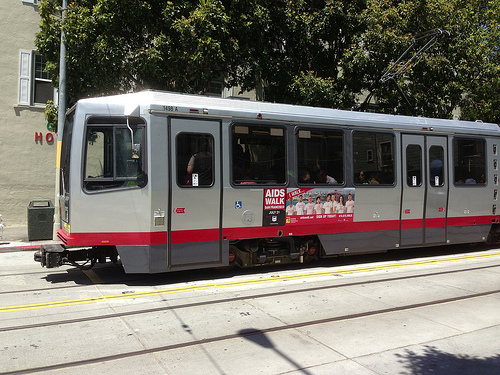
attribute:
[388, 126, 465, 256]
door — is closed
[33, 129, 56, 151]
h o — red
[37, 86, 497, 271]
streetcar — is red, is white, is gray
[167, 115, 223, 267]
door — white, gray, red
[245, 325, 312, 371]
shadow — power lines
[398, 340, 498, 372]
shadow — power lines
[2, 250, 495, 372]
shadow — power lines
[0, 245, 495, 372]
pavement — gray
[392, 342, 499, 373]
shadow — tree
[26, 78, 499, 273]
trolley — red, white, gray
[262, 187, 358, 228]
sign — advertisement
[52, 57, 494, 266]
train — is silver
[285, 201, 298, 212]
t-shirts — is white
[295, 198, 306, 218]
t-shirts — is white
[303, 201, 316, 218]
t-shirts — is white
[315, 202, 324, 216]
t-shirts — is white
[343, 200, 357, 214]
t-shirts — is white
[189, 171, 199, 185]
sticker — white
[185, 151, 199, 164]
shirt — gray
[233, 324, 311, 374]
shadow — parking meter